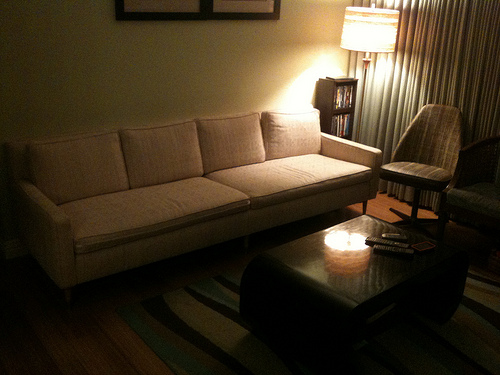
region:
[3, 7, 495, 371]
a living room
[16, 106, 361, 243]
a four people couch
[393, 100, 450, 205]
a chair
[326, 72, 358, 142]
a small wooden bookshelf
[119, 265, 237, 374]
a rug on the floor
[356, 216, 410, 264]
an assortment of remotes on a coffee table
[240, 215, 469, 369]
a black coffee table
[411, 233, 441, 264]
a red tablet on a coffee table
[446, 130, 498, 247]
an armchair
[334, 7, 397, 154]
a standing lamp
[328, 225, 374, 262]
light reflecting on the coffee table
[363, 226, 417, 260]
three black remote controls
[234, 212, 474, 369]
small, dark coffee table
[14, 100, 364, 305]
small white couch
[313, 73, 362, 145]
small bookshelf in the corner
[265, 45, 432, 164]
light streaming out of the lamp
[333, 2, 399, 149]
tall lamp that is turned on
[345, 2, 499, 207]
curtains are drawn shut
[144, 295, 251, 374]
thick brown line on the rug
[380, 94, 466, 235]
chair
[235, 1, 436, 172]
light is dim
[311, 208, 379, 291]
light is dim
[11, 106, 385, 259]
sofa is light colored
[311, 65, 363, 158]
shelves lean against the wall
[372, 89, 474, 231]
the chair has no arms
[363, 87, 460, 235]
chair has wheels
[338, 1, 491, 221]
curtains are drawn on window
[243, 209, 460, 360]
coffee table is dark colored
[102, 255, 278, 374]
rug is sitting on floor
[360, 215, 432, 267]
three remotes siting on table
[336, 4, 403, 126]
a lamp in the corner of a room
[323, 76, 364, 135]
a shelf near a lamp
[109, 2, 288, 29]
part of a picture with brown frame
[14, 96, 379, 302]
couch on a room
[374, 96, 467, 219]
chair is black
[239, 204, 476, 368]
center table if front of couch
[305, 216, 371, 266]
light reflect on the table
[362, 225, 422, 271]
three remote controls on a table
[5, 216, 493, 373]
multi-colored carpet in a room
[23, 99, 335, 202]
rest back of couch has four cushions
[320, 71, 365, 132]
case filled with dvds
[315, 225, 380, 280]
reflection of lit lamp on a table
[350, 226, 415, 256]
bunch of black controls on a table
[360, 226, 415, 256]
three black controls on a table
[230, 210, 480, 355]
black table on top of an area rug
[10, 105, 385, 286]
empty couch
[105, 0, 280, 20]
wall art with a brown wooden frame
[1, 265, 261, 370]
area rug covering the floor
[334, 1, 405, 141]
lit lamp in a corner